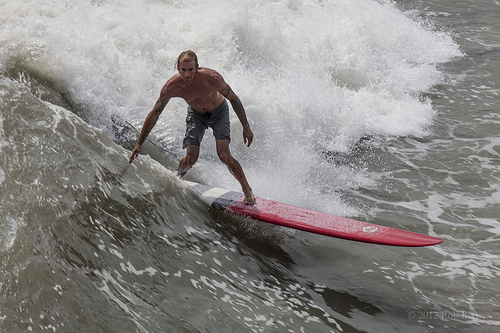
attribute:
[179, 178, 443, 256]
surfboard — red, white, black, long, blue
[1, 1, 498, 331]
water — foamy, green, splashing, dark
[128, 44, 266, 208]
man — surfing, surfer, wet, standing, in surfing stance, shirtless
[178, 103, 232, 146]
shorts — board shorts, gray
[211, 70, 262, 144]
arm — tattooed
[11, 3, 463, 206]
wave — rolling, crashing, mighty, large, very high, white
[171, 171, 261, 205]
feet — bare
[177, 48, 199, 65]
hair — blonde